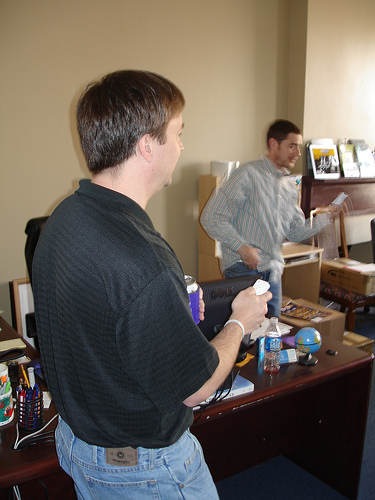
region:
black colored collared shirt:
[29, 176, 207, 454]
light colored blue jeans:
[44, 414, 216, 498]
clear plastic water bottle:
[263, 312, 282, 373]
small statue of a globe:
[295, 326, 322, 367]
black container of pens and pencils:
[14, 360, 46, 433]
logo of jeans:
[104, 444, 139, 467]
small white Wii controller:
[225, 276, 271, 342]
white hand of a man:
[232, 281, 271, 334]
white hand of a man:
[238, 245, 261, 270]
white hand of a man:
[324, 201, 343, 219]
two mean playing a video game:
[27, 73, 361, 496]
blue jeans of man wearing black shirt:
[50, 416, 223, 499]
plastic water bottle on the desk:
[259, 316, 284, 377]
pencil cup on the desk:
[15, 362, 43, 430]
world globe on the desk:
[295, 330, 322, 366]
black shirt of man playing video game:
[30, 186, 208, 444]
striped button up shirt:
[203, 163, 328, 266]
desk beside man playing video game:
[0, 304, 373, 496]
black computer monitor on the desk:
[192, 272, 267, 364]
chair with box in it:
[310, 204, 374, 335]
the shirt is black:
[27, 172, 224, 459]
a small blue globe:
[293, 326, 329, 369]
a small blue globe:
[288, 306, 329, 383]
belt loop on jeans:
[143, 446, 156, 468]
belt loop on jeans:
[90, 445, 101, 465]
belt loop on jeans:
[68, 427, 74, 447]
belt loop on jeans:
[55, 414, 60, 421]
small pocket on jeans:
[184, 445, 200, 472]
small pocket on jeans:
[177, 430, 211, 491]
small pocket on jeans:
[80, 467, 161, 497]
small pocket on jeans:
[53, 435, 72, 468]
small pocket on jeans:
[225, 262, 252, 275]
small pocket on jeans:
[230, 263, 244, 272]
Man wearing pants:
[48, 414, 228, 496]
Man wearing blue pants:
[45, 412, 225, 497]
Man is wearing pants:
[49, 409, 220, 495]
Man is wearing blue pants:
[51, 407, 219, 497]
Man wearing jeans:
[50, 409, 223, 498]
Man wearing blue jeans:
[51, 414, 224, 496]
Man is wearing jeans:
[49, 408, 224, 499]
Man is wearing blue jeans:
[47, 408, 224, 498]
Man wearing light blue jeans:
[53, 412, 229, 498]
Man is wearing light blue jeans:
[50, 410, 224, 498]